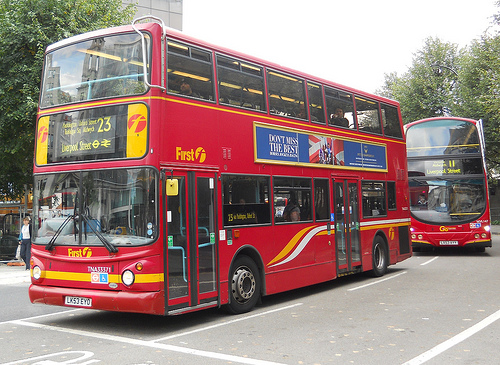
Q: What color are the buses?
A: Red and yellow.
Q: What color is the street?
A: Black.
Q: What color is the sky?
A: Gray.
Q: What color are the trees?
A: Green.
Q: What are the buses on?
A: The street.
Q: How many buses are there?
A: Two.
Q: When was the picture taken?
A: Daytime.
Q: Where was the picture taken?
A: At a bus station.